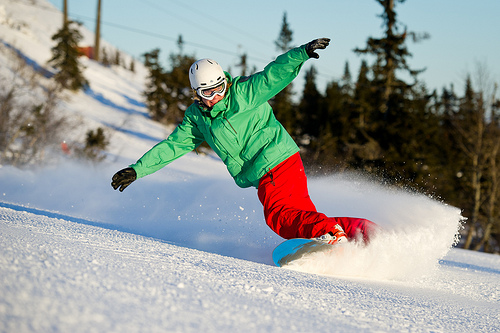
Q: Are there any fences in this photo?
A: No, there are no fences.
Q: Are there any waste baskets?
A: No, there are no waste baskets.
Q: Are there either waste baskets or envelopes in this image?
A: No, there are no waste baskets or envelopes.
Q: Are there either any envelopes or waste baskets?
A: No, there are no waste baskets or envelopes.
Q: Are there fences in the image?
A: No, there are no fences.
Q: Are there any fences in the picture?
A: No, there are no fences.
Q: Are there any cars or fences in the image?
A: No, there are no fences or cars.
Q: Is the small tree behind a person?
A: Yes, the tree is behind a person.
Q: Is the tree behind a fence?
A: No, the tree is behind a person.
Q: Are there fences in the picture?
A: No, there are no fences.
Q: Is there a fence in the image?
A: No, there are no fences.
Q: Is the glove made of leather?
A: Yes, the glove is made of leather.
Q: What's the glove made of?
A: The glove is made of leather.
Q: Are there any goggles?
A: Yes, there are goggles.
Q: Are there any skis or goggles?
A: Yes, there are goggles.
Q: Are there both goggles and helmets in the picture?
A: Yes, there are both goggles and a helmet.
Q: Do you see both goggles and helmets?
A: Yes, there are both goggles and a helmet.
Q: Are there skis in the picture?
A: No, there are no skis.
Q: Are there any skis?
A: No, there are no skis.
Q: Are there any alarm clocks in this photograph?
A: No, there are no alarm clocks.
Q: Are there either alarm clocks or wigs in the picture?
A: No, there are no alarm clocks or wigs.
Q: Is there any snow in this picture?
A: Yes, there is snow.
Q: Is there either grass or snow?
A: Yes, there is snow.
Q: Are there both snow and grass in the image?
A: No, there is snow but no grass.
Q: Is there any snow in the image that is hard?
A: Yes, there is snow that is hard.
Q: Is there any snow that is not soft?
A: Yes, there is hard snow.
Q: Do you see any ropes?
A: No, there are no ropes.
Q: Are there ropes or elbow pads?
A: No, there are no ropes or elbow pads.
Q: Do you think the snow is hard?
A: Yes, the snow is hard.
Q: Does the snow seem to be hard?
A: Yes, the snow is hard.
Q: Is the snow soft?
A: No, the snow is hard.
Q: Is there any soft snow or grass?
A: No, there is snow but it is hard.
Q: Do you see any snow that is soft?
A: No, there is snow but it is hard.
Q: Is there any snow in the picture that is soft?
A: No, there is snow but it is hard.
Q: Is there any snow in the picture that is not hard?
A: No, there is snow but it is hard.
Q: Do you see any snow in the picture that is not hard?
A: No, there is snow but it is hard.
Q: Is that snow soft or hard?
A: The snow is hard.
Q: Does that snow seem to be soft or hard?
A: The snow is hard.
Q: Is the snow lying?
A: Yes, the snow is lying.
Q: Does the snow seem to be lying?
A: Yes, the snow is lying.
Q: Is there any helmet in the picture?
A: Yes, there is a helmet.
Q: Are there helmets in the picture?
A: Yes, there is a helmet.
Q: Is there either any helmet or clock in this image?
A: Yes, there is a helmet.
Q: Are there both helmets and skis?
A: No, there is a helmet but no skis.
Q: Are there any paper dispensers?
A: No, there are no paper dispensers.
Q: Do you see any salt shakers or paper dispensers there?
A: No, there are no paper dispensers or salt shakers.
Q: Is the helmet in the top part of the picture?
A: Yes, the helmet is in the top of the image.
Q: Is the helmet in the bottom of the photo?
A: No, the helmet is in the top of the image.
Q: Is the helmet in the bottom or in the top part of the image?
A: The helmet is in the top of the image.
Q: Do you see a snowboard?
A: Yes, there is a snowboard.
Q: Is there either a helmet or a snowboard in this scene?
A: Yes, there is a snowboard.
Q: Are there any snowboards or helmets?
A: Yes, there is a snowboard.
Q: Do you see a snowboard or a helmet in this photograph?
A: Yes, there is a snowboard.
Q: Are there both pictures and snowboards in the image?
A: No, there is a snowboard but no pictures.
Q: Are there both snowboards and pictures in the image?
A: No, there is a snowboard but no pictures.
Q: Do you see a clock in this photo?
A: No, there are no clocks.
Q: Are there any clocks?
A: No, there are no clocks.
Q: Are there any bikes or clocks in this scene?
A: No, there are no clocks or bikes.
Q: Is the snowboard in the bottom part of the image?
A: Yes, the snowboard is in the bottom of the image.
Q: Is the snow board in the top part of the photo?
A: No, the snow board is in the bottom of the image.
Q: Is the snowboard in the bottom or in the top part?
A: The snowboard is in the bottom of the image.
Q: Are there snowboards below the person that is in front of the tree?
A: Yes, there is a snowboard below the person.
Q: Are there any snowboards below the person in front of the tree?
A: Yes, there is a snowboard below the person.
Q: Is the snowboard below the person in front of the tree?
A: Yes, the snowboard is below the person.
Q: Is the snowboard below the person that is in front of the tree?
A: Yes, the snowboard is below the person.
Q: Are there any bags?
A: No, there are no bags.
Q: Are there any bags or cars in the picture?
A: No, there are no bags or cars.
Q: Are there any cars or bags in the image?
A: No, there are no bags or cars.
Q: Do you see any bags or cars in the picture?
A: No, there are no bags or cars.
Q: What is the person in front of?
A: The person is in front of the tree.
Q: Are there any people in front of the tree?
A: Yes, there is a person in front of the tree.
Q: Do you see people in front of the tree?
A: Yes, there is a person in front of the tree.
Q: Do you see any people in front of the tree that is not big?
A: Yes, there is a person in front of the tree.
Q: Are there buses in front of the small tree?
A: No, there is a person in front of the tree.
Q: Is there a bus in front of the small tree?
A: No, there is a person in front of the tree.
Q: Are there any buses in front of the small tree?
A: No, there is a person in front of the tree.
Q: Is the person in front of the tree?
A: Yes, the person is in front of the tree.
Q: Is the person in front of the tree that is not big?
A: Yes, the person is in front of the tree.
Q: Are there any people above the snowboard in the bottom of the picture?
A: Yes, there is a person above the snowboard.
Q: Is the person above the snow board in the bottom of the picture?
A: Yes, the person is above the snowboard.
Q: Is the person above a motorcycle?
A: No, the person is above the snowboard.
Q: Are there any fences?
A: No, there are no fences.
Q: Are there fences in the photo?
A: No, there are no fences.